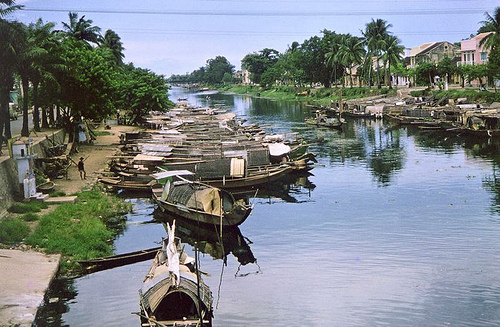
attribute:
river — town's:
[105, 70, 498, 307]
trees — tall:
[367, 19, 402, 90]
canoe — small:
[72, 238, 161, 271]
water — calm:
[314, 183, 496, 311]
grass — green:
[32, 180, 159, 272]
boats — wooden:
[121, 99, 342, 221]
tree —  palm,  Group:
[356, 10, 414, 91]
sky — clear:
[148, 15, 206, 59]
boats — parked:
[101, 101, 319, 321]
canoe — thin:
[76, 245, 167, 267]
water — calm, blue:
[272, 220, 454, 320]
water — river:
[315, 127, 486, 282]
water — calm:
[416, 190, 473, 221]